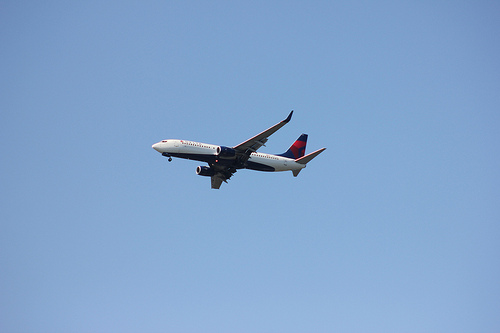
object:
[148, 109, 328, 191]
plane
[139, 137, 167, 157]
nose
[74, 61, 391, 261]
mid air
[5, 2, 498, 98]
sky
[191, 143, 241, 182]
engines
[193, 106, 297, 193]
wings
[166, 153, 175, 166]
wheel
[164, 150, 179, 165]
landing gear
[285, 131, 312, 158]
tail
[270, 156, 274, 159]
windows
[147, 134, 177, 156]
cockpit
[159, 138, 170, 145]
windshield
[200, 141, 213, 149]
people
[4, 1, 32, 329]
left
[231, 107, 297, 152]
right wing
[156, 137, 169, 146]
window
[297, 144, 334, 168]
tail fins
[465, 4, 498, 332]
right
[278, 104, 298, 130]
tip